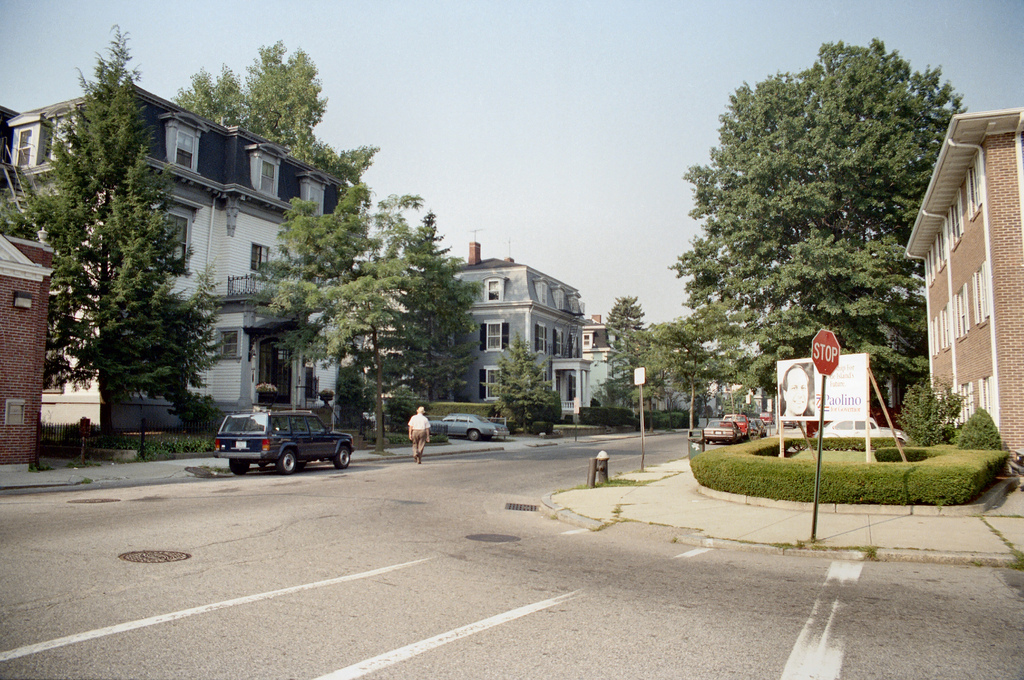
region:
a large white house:
[27, 94, 382, 417]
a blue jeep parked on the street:
[221, 410, 361, 468]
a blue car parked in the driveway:
[427, 410, 508, 445]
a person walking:
[408, 405, 434, 457]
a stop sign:
[811, 325, 841, 544]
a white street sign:
[628, 361, 652, 469]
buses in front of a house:
[688, 443, 986, 504]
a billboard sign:
[764, 361, 876, 422]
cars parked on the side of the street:
[694, 407, 768, 442]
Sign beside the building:
[772, 347, 877, 433]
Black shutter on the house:
[468, 312, 494, 358]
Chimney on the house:
[462, 234, 489, 277]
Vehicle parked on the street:
[213, 395, 354, 473]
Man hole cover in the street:
[109, 544, 192, 567]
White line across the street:
[731, 534, 871, 672]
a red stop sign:
[813, 327, 834, 370]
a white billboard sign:
[772, 358, 861, 415]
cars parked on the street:
[702, 412, 750, 438]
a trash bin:
[683, 424, 699, 448]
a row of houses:
[7, 92, 706, 424]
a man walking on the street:
[402, 402, 429, 461]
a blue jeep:
[215, 412, 362, 464]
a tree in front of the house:
[708, 58, 915, 378]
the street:
[26, 487, 1001, 671]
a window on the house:
[481, 318, 505, 348]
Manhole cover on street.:
[118, 542, 194, 568]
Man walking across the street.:
[405, 405, 432, 466]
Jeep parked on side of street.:
[209, 405, 359, 476]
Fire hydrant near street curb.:
[589, 446, 615, 488]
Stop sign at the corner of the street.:
[801, 323, 841, 543]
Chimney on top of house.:
[466, 240, 483, 261]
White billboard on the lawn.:
[770, 354, 878, 462]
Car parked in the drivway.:
[428, 411, 512, 444]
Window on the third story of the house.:
[479, 276, 508, 305]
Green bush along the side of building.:
[950, 402, 1004, 451]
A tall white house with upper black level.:
[0, 83, 352, 431]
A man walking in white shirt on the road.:
[405, 403, 431, 468]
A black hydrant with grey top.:
[595, 448, 608, 483]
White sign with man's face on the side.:
[773, 350, 872, 464]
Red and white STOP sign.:
[810, 324, 840, 376]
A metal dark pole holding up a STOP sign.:
[807, 372, 828, 540]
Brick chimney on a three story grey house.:
[463, 238, 482, 265]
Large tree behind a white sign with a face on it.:
[667, 39, 968, 426]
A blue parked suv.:
[213, 409, 354, 474]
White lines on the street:
[1, 517, 875, 673]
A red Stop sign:
[794, 310, 848, 383]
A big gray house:
[440, 232, 599, 416]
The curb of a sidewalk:
[525, 475, 1016, 577]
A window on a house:
[465, 301, 516, 356]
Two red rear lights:
[200, 424, 273, 459]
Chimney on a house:
[456, 225, 488, 279]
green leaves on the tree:
[820, 227, 836, 254]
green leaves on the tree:
[822, 307, 873, 337]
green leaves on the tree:
[711, 215, 765, 273]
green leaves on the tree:
[749, 306, 779, 330]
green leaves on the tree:
[401, 253, 447, 324]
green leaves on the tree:
[288, 189, 366, 284]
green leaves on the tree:
[67, 211, 140, 295]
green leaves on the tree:
[352, 278, 385, 337]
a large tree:
[720, 62, 939, 361]